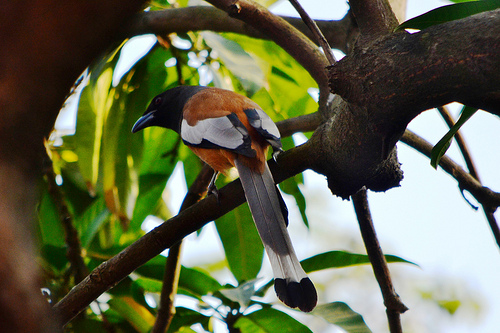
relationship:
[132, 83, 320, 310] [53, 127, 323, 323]
bird standing on branch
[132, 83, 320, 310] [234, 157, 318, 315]
bird has tail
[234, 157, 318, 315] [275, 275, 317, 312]
tail has edge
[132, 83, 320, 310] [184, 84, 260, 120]
bird has back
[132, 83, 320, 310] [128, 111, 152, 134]
bird has beak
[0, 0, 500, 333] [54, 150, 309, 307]
tree has branch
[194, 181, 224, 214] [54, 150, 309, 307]
foot on branch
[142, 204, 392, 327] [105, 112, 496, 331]
leaves in distance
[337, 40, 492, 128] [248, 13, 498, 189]
bark on branch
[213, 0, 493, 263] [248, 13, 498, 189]
tree has branch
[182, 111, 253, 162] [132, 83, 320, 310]
wing on bird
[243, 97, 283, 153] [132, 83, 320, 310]
wing on bird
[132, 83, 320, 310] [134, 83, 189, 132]
bird has head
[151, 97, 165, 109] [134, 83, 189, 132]
eye on head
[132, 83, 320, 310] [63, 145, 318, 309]
bird on branch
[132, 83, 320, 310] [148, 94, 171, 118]
bird has eye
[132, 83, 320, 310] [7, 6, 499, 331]
bird on tree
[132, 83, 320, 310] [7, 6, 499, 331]
bird in tree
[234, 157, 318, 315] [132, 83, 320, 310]
tail of bird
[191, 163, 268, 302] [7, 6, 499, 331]
leaf of tree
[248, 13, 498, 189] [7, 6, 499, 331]
branch of tree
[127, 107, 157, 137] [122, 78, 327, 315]
beak of bird